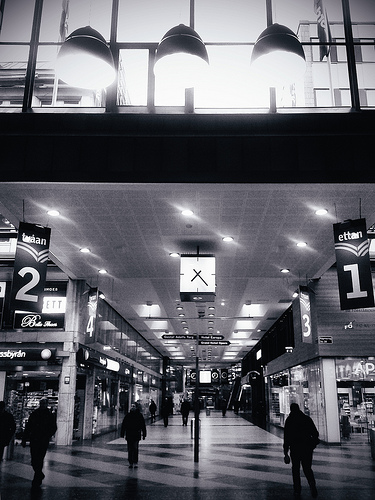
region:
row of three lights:
[49, 19, 308, 94]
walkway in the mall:
[25, 396, 361, 492]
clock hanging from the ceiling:
[175, 255, 216, 299]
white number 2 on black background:
[11, 262, 43, 305]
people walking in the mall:
[3, 367, 322, 493]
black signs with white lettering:
[159, 331, 229, 346]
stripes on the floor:
[8, 440, 367, 496]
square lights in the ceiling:
[135, 290, 259, 368]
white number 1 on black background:
[336, 262, 374, 304]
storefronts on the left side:
[3, 343, 166, 447]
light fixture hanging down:
[151, 51, 212, 91]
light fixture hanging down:
[55, 45, 122, 98]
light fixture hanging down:
[252, 45, 307, 91]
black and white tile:
[163, 444, 272, 498]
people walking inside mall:
[12, 360, 315, 479]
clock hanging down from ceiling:
[184, 255, 214, 290]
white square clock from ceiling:
[184, 258, 220, 288]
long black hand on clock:
[195, 265, 210, 286]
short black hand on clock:
[187, 268, 206, 281]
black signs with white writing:
[151, 332, 226, 350]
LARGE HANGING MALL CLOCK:
[172, 249, 220, 302]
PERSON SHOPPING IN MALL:
[279, 396, 324, 496]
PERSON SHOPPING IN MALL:
[119, 399, 149, 469]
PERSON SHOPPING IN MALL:
[17, 394, 60, 491]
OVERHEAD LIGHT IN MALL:
[292, 237, 311, 252]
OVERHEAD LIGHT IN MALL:
[216, 294, 231, 310]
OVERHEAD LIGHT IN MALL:
[175, 305, 187, 312]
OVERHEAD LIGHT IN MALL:
[181, 319, 187, 325]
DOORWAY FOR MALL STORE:
[69, 373, 88, 446]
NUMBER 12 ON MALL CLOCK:
[194, 255, 202, 265]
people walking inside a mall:
[14, 301, 372, 482]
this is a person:
[105, 396, 163, 472]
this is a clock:
[160, 230, 233, 324]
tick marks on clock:
[176, 248, 222, 297]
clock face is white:
[167, 245, 228, 299]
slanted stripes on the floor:
[83, 417, 289, 498]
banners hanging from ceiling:
[13, 222, 60, 320]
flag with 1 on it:
[317, 201, 373, 316]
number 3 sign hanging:
[281, 268, 318, 349]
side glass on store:
[256, 344, 373, 454]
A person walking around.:
[279, 399, 321, 491]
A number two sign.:
[5, 217, 46, 310]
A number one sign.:
[330, 211, 371, 308]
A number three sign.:
[297, 289, 312, 340]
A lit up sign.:
[176, 248, 214, 297]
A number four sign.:
[84, 283, 99, 344]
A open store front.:
[270, 354, 374, 445]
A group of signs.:
[161, 331, 231, 348]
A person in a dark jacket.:
[117, 402, 148, 468]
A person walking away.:
[20, 394, 59, 487]